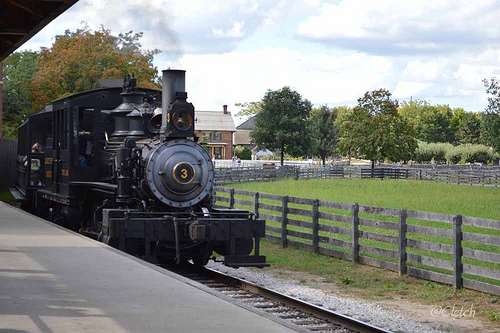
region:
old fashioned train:
[0, 66, 274, 275]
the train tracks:
[165, 263, 392, 332]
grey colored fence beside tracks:
[213, 184, 498, 295]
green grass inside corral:
[218, 175, 498, 285]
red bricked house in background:
[192, 107, 272, 158]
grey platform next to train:
[0, 196, 306, 330]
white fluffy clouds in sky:
[25, 0, 498, 112]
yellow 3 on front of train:
[175, 163, 193, 183]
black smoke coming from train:
[101, 3, 183, 69]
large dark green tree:
[252, 86, 312, 163]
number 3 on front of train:
[171, 157, 201, 183]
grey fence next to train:
[255, 182, 497, 283]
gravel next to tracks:
[228, 223, 413, 329]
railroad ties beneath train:
[181, 235, 263, 331]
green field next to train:
[235, 179, 499, 278]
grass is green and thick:
[320, 188, 487, 252]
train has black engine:
[17, 100, 160, 221]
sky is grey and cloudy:
[178, 10, 274, 111]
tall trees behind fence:
[248, 76, 438, 161]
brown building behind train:
[178, 100, 237, 152]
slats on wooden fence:
[357, 208, 404, 255]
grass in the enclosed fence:
[345, 171, 409, 201]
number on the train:
[170, 163, 198, 184]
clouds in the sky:
[283, 52, 354, 87]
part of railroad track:
[223, 282, 288, 316]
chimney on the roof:
[220, 101, 233, 121]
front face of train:
[148, 144, 212, 205]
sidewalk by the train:
[27, 249, 94, 314]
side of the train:
[42, 155, 68, 195]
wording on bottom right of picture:
[429, 296, 490, 322]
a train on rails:
[1, 54, 271, 293]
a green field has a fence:
[220, 142, 498, 299]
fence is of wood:
[280, 190, 498, 290]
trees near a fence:
[245, 83, 422, 184]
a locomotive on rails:
[9, 56, 276, 291]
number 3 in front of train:
[139, 136, 224, 213]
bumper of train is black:
[96, 194, 283, 281]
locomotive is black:
[9, 54, 274, 281]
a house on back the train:
[196, 94, 241, 162]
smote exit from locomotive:
[108, 0, 197, 80]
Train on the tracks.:
[1, 56, 351, 297]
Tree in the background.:
[240, 84, 347, 170]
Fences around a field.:
[184, 137, 494, 313]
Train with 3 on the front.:
[22, 56, 359, 330]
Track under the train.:
[161, 238, 210, 305]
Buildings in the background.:
[167, 79, 290, 195]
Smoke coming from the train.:
[125, 15, 215, 103]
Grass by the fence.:
[272, 231, 423, 319]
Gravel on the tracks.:
[250, 255, 432, 330]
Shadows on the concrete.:
[30, 212, 168, 324]